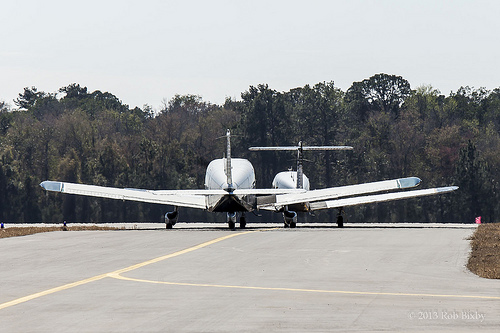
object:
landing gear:
[239, 216, 247, 228]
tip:
[35, 176, 62, 191]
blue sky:
[1, 0, 498, 116]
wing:
[305, 185, 459, 208]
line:
[2, 227, 241, 312]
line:
[110, 271, 499, 303]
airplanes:
[41, 128, 423, 230]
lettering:
[403, 310, 490, 325]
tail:
[294, 141, 303, 186]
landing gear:
[163, 211, 175, 228]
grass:
[466, 220, 500, 279]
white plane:
[127, 109, 326, 240]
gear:
[225, 213, 236, 231]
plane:
[39, 127, 421, 229]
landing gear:
[334, 215, 345, 227]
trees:
[451, 138, 499, 223]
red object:
[475, 212, 484, 228]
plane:
[122, 140, 472, 255]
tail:
[222, 126, 235, 191]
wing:
[184, 185, 291, 199]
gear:
[288, 213, 297, 227]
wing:
[275, 171, 423, 211]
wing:
[36, 175, 210, 209]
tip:
[395, 173, 422, 191]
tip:
[433, 184, 459, 192]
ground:
[0, 216, 499, 329]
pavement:
[0, 221, 500, 329]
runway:
[2, 227, 498, 330]